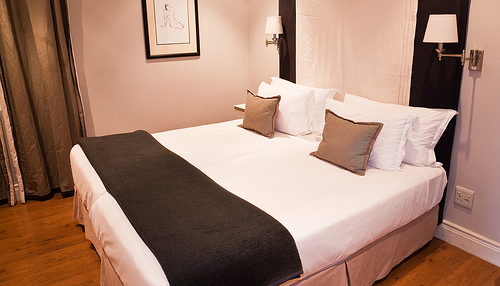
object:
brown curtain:
[0, 0, 84, 207]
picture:
[140, 0, 199, 59]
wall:
[77, 0, 242, 136]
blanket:
[74, 130, 306, 286]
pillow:
[310, 110, 380, 175]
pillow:
[238, 88, 281, 138]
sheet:
[68, 117, 447, 286]